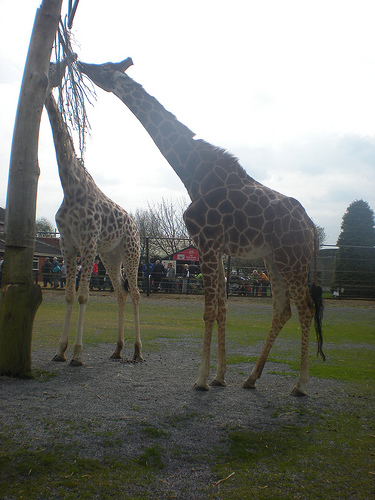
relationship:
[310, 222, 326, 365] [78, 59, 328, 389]
tail of giraffe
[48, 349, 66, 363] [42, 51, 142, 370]
hoof on giraffe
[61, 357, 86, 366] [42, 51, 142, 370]
hoof on giraffe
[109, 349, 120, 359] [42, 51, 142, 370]
hoof on giraffe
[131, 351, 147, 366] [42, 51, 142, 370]
hoof on giraffe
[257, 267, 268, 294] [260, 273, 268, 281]
person in shirt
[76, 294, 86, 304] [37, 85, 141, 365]
knee on giraffe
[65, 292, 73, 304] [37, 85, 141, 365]
knee on giraffe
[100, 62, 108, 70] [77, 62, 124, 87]
eye on face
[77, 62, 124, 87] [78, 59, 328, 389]
face of giraffe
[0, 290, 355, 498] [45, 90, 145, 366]
pen with giraffe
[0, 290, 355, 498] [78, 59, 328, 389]
pen with giraffe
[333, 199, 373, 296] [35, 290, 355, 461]
bush growing from ground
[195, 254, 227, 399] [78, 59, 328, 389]
legs of giraffe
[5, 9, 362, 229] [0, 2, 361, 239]
clouds in sky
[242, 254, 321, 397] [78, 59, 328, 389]
legs of the giraffe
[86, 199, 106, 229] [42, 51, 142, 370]
pattern on the giraffe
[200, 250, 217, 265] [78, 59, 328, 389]
spot on the giraffe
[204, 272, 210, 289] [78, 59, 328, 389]
spot on giraffe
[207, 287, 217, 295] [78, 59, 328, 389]
spot on giraffe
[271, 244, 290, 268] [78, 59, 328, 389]
spot on giraffe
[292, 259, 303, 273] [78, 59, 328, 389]
spot on giraffe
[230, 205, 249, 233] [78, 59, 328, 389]
spot on giraffe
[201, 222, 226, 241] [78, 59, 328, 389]
spot on giraffe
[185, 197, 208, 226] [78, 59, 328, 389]
spot on giraffe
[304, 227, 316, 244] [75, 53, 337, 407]
spot on giraffe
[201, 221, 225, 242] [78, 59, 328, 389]
spot on  a giraffe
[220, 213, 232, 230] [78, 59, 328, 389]
spot on  a giraffe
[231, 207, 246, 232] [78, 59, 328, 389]
spot on  a giraffe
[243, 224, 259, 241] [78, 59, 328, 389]
spot on  a giraffe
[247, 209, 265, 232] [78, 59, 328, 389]
spot on  a giraffe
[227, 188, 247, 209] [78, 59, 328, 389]
spot on  a giraffe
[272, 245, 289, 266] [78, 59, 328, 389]
spot on  a giraffe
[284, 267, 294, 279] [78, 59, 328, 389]
spot on  a giraffe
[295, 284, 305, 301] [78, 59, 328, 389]
spot on  a giraffe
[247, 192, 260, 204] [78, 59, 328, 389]
spot on  a giraffe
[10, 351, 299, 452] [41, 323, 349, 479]
gravel in the grass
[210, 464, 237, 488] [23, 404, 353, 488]
twig on the ground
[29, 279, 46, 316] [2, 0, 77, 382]
knothole on tree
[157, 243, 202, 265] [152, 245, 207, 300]
facade of building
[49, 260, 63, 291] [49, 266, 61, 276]
woman wearing shirt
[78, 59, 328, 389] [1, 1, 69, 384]
giraffe eating from tree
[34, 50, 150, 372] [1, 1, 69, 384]
giraffe eating from tree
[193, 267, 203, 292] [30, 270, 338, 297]
person behind fence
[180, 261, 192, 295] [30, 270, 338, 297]
person behind fence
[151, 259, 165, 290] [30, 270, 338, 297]
person behind fence